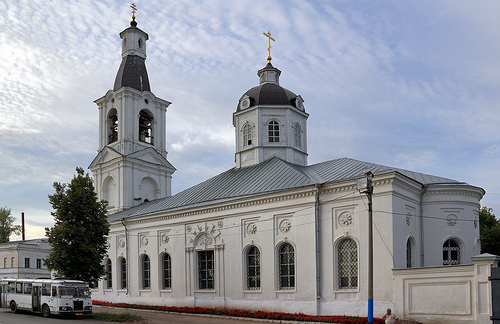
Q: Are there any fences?
A: No, there are no fences.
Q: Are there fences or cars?
A: No, there are no fences or cars.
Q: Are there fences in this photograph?
A: No, there are no fences.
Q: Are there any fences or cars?
A: No, there are no fences or cars.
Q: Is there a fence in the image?
A: No, there are no fences.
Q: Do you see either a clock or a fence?
A: No, there are no fences or clocks.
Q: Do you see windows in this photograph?
A: Yes, there is a window.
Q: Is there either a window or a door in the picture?
A: Yes, there is a window.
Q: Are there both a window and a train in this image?
A: No, there is a window but no trains.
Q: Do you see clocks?
A: No, there are no clocks.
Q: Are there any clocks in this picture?
A: No, there are no clocks.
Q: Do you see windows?
A: Yes, there is a window.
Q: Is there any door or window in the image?
A: Yes, there is a window.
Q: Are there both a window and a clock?
A: No, there is a window but no clocks.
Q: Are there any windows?
A: Yes, there is a window.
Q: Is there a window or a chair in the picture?
A: Yes, there is a window.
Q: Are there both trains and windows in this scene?
A: No, there is a window but no trains.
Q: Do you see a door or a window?
A: Yes, there is a window.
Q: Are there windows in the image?
A: Yes, there is a window.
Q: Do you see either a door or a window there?
A: Yes, there is a window.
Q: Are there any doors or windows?
A: Yes, there is a window.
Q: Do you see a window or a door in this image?
A: Yes, there is a window.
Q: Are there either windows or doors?
A: Yes, there is a window.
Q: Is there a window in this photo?
A: Yes, there is a window.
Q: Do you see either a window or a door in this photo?
A: Yes, there is a window.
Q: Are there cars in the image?
A: No, there are no cars.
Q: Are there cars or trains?
A: No, there are no cars or trains.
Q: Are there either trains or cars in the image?
A: No, there are no cars or trains.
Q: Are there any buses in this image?
A: Yes, there is a bus.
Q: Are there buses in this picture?
A: Yes, there is a bus.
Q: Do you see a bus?
A: Yes, there is a bus.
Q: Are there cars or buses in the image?
A: Yes, there is a bus.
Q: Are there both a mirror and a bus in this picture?
A: No, there is a bus but no mirrors.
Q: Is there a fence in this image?
A: No, there are no fences.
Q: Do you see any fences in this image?
A: No, there are no fences.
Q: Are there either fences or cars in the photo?
A: No, there are no fences or cars.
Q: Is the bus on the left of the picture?
A: Yes, the bus is on the left of the image.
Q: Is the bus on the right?
A: No, the bus is on the left of the image.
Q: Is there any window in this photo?
A: Yes, there is a window.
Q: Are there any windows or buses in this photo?
A: Yes, there is a window.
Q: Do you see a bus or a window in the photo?
A: Yes, there is a window.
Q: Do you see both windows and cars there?
A: No, there is a window but no cars.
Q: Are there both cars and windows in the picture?
A: No, there is a window but no cars.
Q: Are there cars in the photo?
A: No, there are no cars.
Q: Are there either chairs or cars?
A: No, there are no cars or chairs.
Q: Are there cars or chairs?
A: No, there are no cars or chairs.